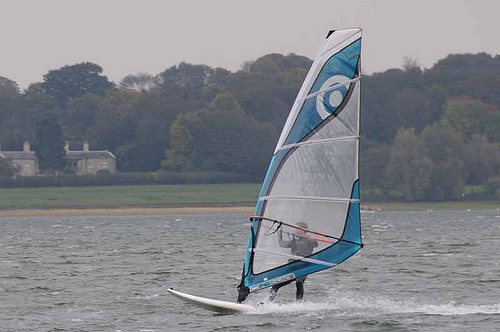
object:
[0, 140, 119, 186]
house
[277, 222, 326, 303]
man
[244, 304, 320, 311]
white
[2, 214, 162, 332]
water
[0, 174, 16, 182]
hedges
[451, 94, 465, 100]
red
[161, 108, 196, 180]
trees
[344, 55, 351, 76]
blue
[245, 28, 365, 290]
sail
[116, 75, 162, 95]
tree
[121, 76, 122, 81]
leaves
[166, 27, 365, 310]
equipment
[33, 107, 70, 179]
tree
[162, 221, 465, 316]
surfing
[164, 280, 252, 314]
front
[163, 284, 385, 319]
surfboard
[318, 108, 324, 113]
white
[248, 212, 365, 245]
handle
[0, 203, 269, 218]
beach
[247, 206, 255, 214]
sand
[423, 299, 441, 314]
wake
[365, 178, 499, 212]
shore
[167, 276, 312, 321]
board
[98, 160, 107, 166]
stone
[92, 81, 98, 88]
color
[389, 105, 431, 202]
trees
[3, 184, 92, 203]
trimmed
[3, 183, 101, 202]
grass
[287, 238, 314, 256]
black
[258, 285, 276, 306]
spray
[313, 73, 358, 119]
circle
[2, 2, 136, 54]
skies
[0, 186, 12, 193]
green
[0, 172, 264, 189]
row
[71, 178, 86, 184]
green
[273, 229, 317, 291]
wetsuit